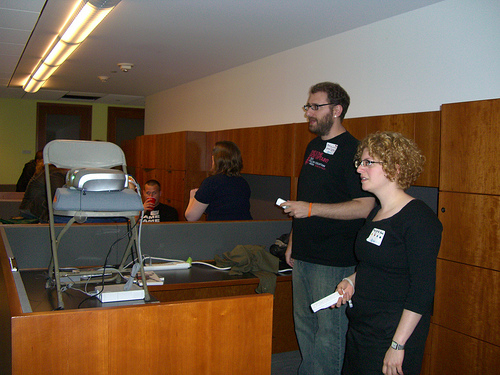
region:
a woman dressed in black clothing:
[345, 127, 476, 373]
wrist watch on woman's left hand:
[385, 338, 405, 355]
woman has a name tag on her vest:
[363, 226, 392, 251]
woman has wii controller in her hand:
[305, 282, 350, 316]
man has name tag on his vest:
[320, 140, 340, 157]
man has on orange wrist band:
[305, 195, 312, 225]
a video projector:
[65, 159, 130, 194]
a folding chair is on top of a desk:
[20, 139, 168, 312]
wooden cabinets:
[440, 107, 497, 372]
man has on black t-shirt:
[296, 128, 356, 267]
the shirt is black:
[281, 128, 371, 275]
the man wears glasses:
[296, 69, 354, 141]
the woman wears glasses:
[342, 142, 404, 176]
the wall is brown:
[45, 288, 250, 368]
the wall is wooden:
[75, 272, 257, 364]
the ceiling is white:
[139, 12, 235, 72]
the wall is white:
[204, 83, 280, 113]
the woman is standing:
[347, 114, 436, 370]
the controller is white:
[297, 267, 357, 321]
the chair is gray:
[38, 120, 168, 291]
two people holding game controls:
[272, 70, 441, 370]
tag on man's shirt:
[317, 134, 350, 161]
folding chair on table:
[37, 134, 159, 311]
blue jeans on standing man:
[281, 247, 371, 373]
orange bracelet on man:
[300, 196, 315, 224]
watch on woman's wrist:
[382, 327, 414, 357]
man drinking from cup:
[129, 174, 184, 230]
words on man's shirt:
[300, 144, 333, 180]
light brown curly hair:
[365, 129, 425, 194]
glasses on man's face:
[300, 97, 325, 116]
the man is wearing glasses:
[291, 75, 372, 176]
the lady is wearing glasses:
[358, 113, 427, 219]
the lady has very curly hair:
[353, 133, 425, 210]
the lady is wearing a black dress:
[324, 198, 444, 360]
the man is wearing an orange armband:
[295, 130, 391, 297]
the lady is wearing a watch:
[388, 325, 416, 371]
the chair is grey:
[23, 116, 174, 299]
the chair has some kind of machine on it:
[22, 147, 167, 202]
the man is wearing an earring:
[281, 100, 356, 129]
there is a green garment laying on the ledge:
[211, 237, 276, 298]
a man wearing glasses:
[298, 79, 351, 139]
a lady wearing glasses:
[350, 132, 428, 197]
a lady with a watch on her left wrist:
[386, 335, 411, 357]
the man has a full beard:
[296, 82, 349, 142]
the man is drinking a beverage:
[136, 175, 168, 222]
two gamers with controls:
[268, 191, 348, 318]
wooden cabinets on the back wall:
[128, 97, 496, 373]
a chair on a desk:
[37, 137, 252, 361]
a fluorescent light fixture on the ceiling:
[6, 0, 122, 102]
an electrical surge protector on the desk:
[133, 257, 195, 274]